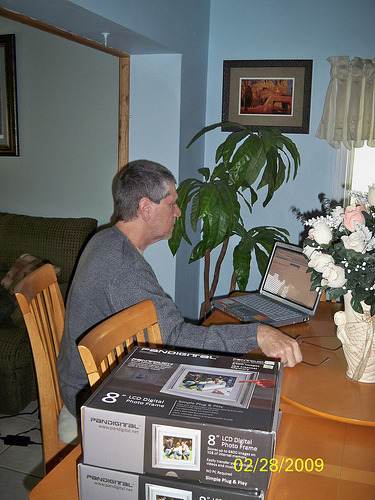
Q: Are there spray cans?
A: No, there are no spray cans.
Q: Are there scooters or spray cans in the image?
A: No, there are no spray cans or scooters.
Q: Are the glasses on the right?
A: Yes, the glasses are on the right of the image.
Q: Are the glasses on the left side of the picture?
A: No, the glasses are on the right of the image.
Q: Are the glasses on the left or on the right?
A: The glasses are on the right of the image.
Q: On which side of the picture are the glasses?
A: The glasses are on the right of the image.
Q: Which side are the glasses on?
A: The glasses are on the right of the image.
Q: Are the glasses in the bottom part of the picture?
A: Yes, the glasses are in the bottom of the image.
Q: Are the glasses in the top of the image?
A: No, the glasses are in the bottom of the image.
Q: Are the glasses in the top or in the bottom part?
A: The glasses are in the bottom of the image.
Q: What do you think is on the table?
A: The glasses are on the table.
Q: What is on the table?
A: The glasses are on the table.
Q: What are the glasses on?
A: The glasses are on the table.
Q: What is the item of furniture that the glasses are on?
A: The piece of furniture is a table.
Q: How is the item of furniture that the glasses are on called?
A: The piece of furniture is a table.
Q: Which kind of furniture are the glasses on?
A: The glasses are on the table.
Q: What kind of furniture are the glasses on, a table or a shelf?
A: The glasses are on a table.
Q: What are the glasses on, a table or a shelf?
A: The glasses are on a table.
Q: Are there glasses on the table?
A: Yes, there are glasses on the table.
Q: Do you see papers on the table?
A: No, there are glasses on the table.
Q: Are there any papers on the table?
A: No, there are glasses on the table.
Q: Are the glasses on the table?
A: Yes, the glasses are on the table.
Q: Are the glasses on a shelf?
A: No, the glasses are on the table.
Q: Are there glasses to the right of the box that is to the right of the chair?
A: Yes, there are glasses to the right of the box.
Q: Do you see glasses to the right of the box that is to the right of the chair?
A: Yes, there are glasses to the right of the box.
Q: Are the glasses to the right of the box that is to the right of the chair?
A: Yes, the glasses are to the right of the box.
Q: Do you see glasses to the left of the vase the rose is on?
A: Yes, there are glasses to the left of the vase.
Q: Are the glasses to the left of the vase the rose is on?
A: Yes, the glasses are to the left of the vase.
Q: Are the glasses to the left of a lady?
A: No, the glasses are to the left of the vase.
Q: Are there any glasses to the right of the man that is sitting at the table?
A: Yes, there are glasses to the right of the man.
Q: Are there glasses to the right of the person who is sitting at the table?
A: Yes, there are glasses to the right of the man.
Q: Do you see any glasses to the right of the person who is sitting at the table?
A: Yes, there are glasses to the right of the man.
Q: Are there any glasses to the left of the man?
A: No, the glasses are to the right of the man.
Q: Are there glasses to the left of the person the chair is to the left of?
A: No, the glasses are to the right of the man.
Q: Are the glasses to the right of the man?
A: Yes, the glasses are to the right of the man.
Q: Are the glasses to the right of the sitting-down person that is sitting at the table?
A: Yes, the glasses are to the right of the man.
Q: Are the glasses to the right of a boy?
A: No, the glasses are to the right of the man.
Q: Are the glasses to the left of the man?
A: No, the glasses are to the right of the man.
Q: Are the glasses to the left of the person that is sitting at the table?
A: No, the glasses are to the right of the man.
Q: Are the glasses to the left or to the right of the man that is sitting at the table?
A: The glasses are to the right of the man.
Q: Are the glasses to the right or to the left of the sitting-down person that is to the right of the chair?
A: The glasses are to the right of the man.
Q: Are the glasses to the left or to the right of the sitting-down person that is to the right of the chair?
A: The glasses are to the right of the man.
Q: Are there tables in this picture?
A: Yes, there is a table.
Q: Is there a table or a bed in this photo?
A: Yes, there is a table.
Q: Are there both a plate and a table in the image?
A: No, there is a table but no plates.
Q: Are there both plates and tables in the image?
A: No, there is a table but no plates.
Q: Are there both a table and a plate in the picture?
A: No, there is a table but no plates.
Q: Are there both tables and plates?
A: No, there is a table but no plates.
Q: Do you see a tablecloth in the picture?
A: No, there are no tablecloths.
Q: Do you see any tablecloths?
A: No, there are no tablecloths.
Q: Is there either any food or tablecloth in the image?
A: No, there are no tablecloths or food.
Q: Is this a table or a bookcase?
A: This is a table.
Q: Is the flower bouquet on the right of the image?
A: Yes, the flower bouquet is on the right of the image.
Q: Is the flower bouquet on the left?
A: No, the flower bouquet is on the right of the image.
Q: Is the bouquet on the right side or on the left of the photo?
A: The bouquet is on the right of the image.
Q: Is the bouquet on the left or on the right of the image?
A: The bouquet is on the right of the image.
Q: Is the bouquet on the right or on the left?
A: The bouquet is on the right of the image.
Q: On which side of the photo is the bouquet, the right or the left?
A: The bouquet is on the right of the image.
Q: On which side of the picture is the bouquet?
A: The bouquet is on the right of the image.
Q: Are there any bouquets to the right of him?
A: Yes, there is a bouquet to the right of the man.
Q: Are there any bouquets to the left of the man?
A: No, the bouquet is to the right of the man.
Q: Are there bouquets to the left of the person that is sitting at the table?
A: No, the bouquet is to the right of the man.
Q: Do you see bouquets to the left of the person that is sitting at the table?
A: No, the bouquet is to the right of the man.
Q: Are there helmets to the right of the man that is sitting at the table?
A: No, there is a bouquet to the right of the man.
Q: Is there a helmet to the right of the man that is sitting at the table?
A: No, there is a bouquet to the right of the man.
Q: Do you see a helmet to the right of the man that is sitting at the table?
A: No, there is a bouquet to the right of the man.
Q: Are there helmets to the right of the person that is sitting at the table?
A: No, there is a bouquet to the right of the man.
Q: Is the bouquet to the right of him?
A: Yes, the bouquet is to the right of the man.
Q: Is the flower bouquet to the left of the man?
A: No, the flower bouquet is to the right of the man.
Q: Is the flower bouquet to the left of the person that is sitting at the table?
A: No, the flower bouquet is to the right of the man.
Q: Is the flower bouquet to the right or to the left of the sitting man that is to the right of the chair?
A: The flower bouquet is to the right of the man.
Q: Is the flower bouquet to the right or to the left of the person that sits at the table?
A: The flower bouquet is to the right of the man.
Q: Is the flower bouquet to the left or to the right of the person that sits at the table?
A: The flower bouquet is to the right of the man.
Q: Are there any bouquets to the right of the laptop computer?
A: Yes, there is a bouquet to the right of the laptop computer.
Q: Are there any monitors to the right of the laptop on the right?
A: No, there is a bouquet to the right of the laptop.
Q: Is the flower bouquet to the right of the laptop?
A: Yes, the flower bouquet is to the right of the laptop.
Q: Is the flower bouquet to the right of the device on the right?
A: Yes, the flower bouquet is to the right of the laptop.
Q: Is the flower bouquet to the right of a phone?
A: No, the flower bouquet is to the right of the laptop.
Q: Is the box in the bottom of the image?
A: Yes, the box is in the bottom of the image.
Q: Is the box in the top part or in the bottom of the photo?
A: The box is in the bottom of the image.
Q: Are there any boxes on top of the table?
A: Yes, there is a box on top of the table.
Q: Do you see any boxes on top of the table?
A: Yes, there is a box on top of the table.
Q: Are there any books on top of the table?
A: No, there is a box on top of the table.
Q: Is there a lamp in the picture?
A: No, there are no lamps.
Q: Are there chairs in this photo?
A: Yes, there is a chair.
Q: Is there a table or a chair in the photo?
A: Yes, there is a chair.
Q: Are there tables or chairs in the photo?
A: Yes, there is a chair.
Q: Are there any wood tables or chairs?
A: Yes, there is a wood chair.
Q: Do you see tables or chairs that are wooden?
A: Yes, the chair is wooden.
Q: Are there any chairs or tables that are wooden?
A: Yes, the chair is wooden.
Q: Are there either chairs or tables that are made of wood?
A: Yes, the chair is made of wood.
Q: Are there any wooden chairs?
A: Yes, there is a wood chair.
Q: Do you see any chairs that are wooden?
A: Yes, there is a chair that is wooden.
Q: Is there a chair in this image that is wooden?
A: Yes, there is a chair that is wooden.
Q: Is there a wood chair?
A: Yes, there is a chair that is made of wood.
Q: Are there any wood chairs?
A: Yes, there is a chair that is made of wood.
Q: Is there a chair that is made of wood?
A: Yes, there is a chair that is made of wood.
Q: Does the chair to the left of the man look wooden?
A: Yes, the chair is wooden.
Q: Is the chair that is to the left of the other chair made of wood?
A: Yes, the chair is made of wood.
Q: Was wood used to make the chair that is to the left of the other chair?
A: Yes, the chair is made of wood.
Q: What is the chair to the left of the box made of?
A: The chair is made of wood.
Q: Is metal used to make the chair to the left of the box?
A: No, the chair is made of wood.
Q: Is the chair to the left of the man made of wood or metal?
A: The chair is made of wood.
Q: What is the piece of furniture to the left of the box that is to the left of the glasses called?
A: The piece of furniture is a chair.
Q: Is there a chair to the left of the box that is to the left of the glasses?
A: Yes, there is a chair to the left of the box.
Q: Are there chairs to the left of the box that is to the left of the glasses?
A: Yes, there is a chair to the left of the box.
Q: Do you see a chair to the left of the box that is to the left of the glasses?
A: Yes, there is a chair to the left of the box.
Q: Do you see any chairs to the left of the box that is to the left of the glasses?
A: Yes, there is a chair to the left of the box.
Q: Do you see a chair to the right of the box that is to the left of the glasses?
A: No, the chair is to the left of the box.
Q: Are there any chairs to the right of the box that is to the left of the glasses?
A: No, the chair is to the left of the box.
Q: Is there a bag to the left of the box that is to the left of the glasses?
A: No, there is a chair to the left of the box.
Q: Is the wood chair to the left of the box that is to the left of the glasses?
A: Yes, the chair is to the left of the box.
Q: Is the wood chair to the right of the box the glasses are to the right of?
A: No, the chair is to the left of the box.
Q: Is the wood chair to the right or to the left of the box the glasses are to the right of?
A: The chair is to the left of the box.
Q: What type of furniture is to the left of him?
A: The piece of furniture is a chair.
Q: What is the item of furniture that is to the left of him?
A: The piece of furniture is a chair.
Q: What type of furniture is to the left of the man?
A: The piece of furniture is a chair.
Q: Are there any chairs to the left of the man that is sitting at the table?
A: Yes, there is a chair to the left of the man.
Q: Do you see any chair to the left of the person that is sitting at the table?
A: Yes, there is a chair to the left of the man.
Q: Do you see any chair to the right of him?
A: No, the chair is to the left of the man.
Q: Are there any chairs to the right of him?
A: No, the chair is to the left of the man.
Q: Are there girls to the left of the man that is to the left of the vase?
A: No, there is a chair to the left of the man.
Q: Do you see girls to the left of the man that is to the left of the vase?
A: No, there is a chair to the left of the man.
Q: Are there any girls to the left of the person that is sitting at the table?
A: No, there is a chair to the left of the man.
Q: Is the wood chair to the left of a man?
A: Yes, the chair is to the left of a man.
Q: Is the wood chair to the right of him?
A: No, the chair is to the left of the man.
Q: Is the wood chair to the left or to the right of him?
A: The chair is to the left of the man.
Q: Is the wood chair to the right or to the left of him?
A: The chair is to the left of the man.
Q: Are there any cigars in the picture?
A: No, there are no cigars.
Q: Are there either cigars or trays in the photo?
A: No, there are no cigars or trays.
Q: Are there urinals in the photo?
A: No, there are no urinals.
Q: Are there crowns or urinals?
A: No, there are no urinals or crowns.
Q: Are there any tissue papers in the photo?
A: No, there are no tissue papers.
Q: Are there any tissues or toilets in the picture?
A: No, there are no tissues or toilets.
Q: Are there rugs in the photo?
A: No, there are no rugs.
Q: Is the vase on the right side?
A: Yes, the vase is on the right of the image.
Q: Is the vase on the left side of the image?
A: No, the vase is on the right of the image.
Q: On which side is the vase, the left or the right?
A: The vase is on the right of the image.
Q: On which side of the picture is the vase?
A: The vase is on the right of the image.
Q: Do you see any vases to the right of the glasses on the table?
A: Yes, there is a vase to the right of the glasses.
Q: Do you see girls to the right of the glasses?
A: No, there is a vase to the right of the glasses.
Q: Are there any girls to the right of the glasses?
A: No, there is a vase to the right of the glasses.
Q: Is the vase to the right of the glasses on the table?
A: Yes, the vase is to the right of the glasses.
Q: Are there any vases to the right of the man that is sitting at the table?
A: Yes, there is a vase to the right of the man.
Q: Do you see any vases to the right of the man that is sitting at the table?
A: Yes, there is a vase to the right of the man.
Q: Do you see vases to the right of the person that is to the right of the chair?
A: Yes, there is a vase to the right of the man.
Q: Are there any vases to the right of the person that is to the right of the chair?
A: Yes, there is a vase to the right of the man.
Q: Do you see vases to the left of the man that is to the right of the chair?
A: No, the vase is to the right of the man.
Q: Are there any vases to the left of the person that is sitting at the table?
A: No, the vase is to the right of the man.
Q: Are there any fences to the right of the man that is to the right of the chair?
A: No, there is a vase to the right of the man.